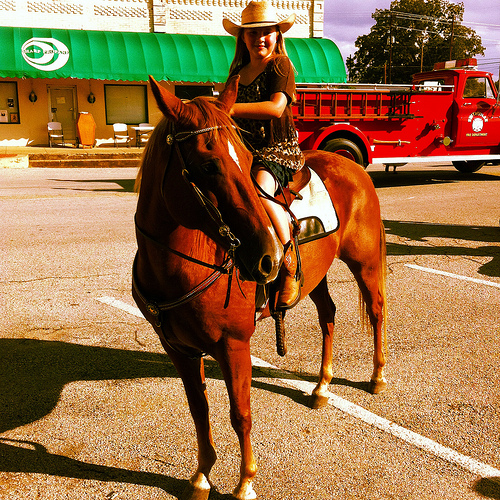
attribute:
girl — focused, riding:
[221, 2, 306, 310]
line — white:
[406, 261, 498, 289]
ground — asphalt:
[4, 167, 135, 499]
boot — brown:
[278, 238, 306, 312]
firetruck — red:
[295, 59, 498, 161]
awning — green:
[2, 29, 350, 85]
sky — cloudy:
[322, 2, 372, 37]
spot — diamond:
[227, 139, 243, 171]